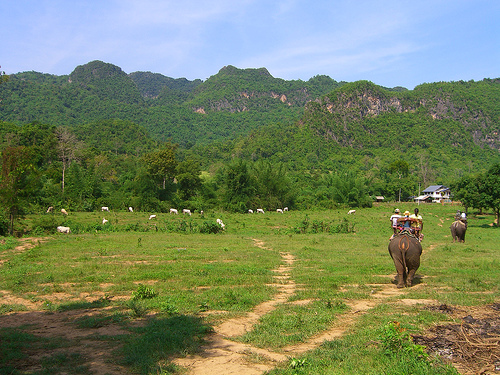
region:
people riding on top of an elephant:
[383, 210, 418, 233]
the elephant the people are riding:
[382, 235, 418, 285]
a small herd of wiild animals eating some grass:
[42, 201, 367, 231]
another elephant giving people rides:
[446, 217, 466, 242]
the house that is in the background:
[411, 185, 446, 200]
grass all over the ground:
[50, 245, 405, 350]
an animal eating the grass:
[213, 215, 222, 230]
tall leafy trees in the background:
[5, 70, 495, 200]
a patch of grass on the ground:
[413, 303, 499, 371]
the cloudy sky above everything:
[5, 2, 492, 81]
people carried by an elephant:
[388, 203, 430, 279]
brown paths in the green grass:
[176, 238, 320, 373]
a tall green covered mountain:
[151, 82, 397, 152]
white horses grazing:
[53, 220, 80, 235]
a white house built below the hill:
[417, 180, 449, 205]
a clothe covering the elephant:
[393, 237, 413, 252]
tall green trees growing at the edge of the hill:
[14, 128, 101, 200]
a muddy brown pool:
[425, 296, 499, 373]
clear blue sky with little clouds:
[258, 29, 447, 88]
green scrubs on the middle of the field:
[296, 216, 350, 236]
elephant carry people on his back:
[379, 200, 431, 290]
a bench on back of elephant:
[387, 216, 425, 291]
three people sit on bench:
[387, 203, 427, 243]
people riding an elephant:
[385, 202, 430, 290]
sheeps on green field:
[39, 192, 373, 240]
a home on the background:
[411, 178, 461, 206]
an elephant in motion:
[444, 208, 472, 248]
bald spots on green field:
[6, 225, 388, 373]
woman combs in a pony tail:
[410, 205, 424, 226]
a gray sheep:
[39, 200, 61, 220]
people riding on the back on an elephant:
[382, 205, 426, 293]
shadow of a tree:
[0, 287, 226, 369]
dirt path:
[220, 211, 301, 373]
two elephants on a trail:
[386, 207, 471, 291]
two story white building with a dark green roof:
[411, 182, 454, 206]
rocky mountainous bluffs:
[1, 58, 497, 125]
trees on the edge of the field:
[1, 117, 498, 224]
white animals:
[48, 201, 360, 236]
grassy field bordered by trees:
[3, 202, 493, 372]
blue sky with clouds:
[1, 1, 497, 84]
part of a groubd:
[225, 339, 244, 366]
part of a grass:
[208, 283, 235, 321]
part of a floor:
[226, 357, 237, 368]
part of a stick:
[456, 328, 481, 355]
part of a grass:
[171, 310, 203, 346]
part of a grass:
[206, 267, 224, 290]